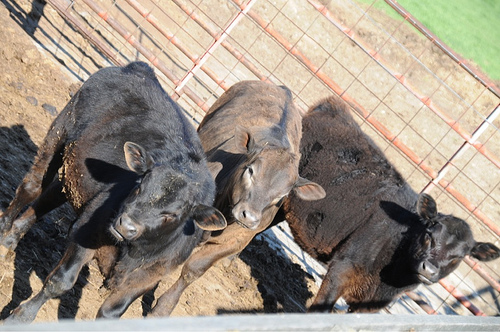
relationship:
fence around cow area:
[8, 2, 498, 329] [18, 46, 330, 330]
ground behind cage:
[200, 265, 245, 311] [137, 18, 362, 77]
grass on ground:
[432, 9, 485, 41] [200, 265, 245, 311]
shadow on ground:
[2, 117, 45, 234] [5, 6, 372, 310]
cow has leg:
[328, 95, 498, 304] [319, 261, 354, 308]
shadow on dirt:
[252, 238, 306, 305] [207, 272, 293, 307]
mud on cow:
[53, 157, 84, 207] [20, 55, 220, 327]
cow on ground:
[10, 60, 228, 330] [5, 10, 337, 306]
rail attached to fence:
[26, 15, 498, 301] [50, 3, 499, 308]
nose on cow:
[110, 213, 136, 239] [0, 65, 231, 315]